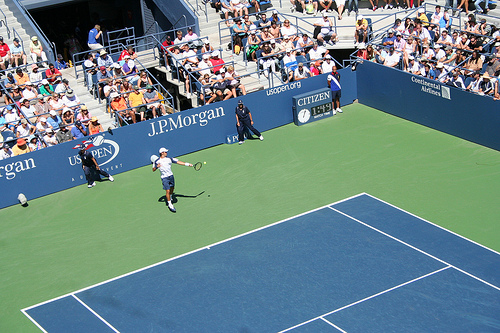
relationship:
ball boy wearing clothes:
[234, 99, 266, 146] [239, 112, 253, 132]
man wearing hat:
[151, 146, 192, 212] [158, 145, 170, 153]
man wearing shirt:
[326, 65, 345, 115] [145, 143, 206, 218]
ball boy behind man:
[234, 99, 263, 144] [151, 146, 197, 214]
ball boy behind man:
[72, 147, 114, 187] [151, 146, 197, 214]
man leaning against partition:
[328, 65, 341, 114] [2, 64, 357, 209]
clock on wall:
[287, 85, 340, 127] [1, 61, 358, 211]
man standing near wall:
[151, 146, 197, 214] [1, 61, 358, 211]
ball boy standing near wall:
[234, 99, 266, 146] [1, 61, 358, 211]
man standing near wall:
[326, 65, 345, 115] [1, 61, 358, 211]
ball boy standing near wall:
[72, 144, 116, 189] [1, 61, 358, 211]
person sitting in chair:
[312, 11, 336, 47] [324, 35, 331, 44]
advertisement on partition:
[148, 102, 228, 137] [0, 55, 500, 214]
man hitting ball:
[151, 146, 197, 214] [202, 160, 208, 164]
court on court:
[0, 97, 499, 331] [0, 97, 499, 331]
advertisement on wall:
[148, 102, 228, 137] [1, 61, 358, 211]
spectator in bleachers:
[0, 0, 500, 167] [0, 3, 498, 162]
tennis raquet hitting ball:
[184, 158, 205, 176] [200, 161, 204, 165]